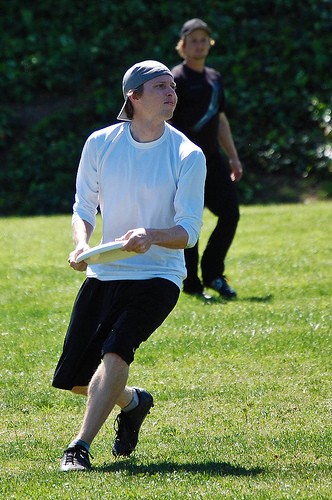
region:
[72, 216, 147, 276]
White frisbee in hands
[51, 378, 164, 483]
Man is wearing cleats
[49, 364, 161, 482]
Man's cleats are black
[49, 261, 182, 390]
Man's black athletic shorts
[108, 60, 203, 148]
Man has hat on backwards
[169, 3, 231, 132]
Man in back is standing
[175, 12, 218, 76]
Man in back is wearing hat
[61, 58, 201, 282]
Man is about to throw frisbee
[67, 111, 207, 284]
White long sleeved shirt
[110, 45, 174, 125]
Grey baseball cap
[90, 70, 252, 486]
BOY PLAYING FRISBEE ON FIELD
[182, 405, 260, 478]
SHORT GRASS ON FIELD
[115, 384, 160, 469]
BLACK CLEAT ON BOY'S FOOT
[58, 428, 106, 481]
BLACK CLEAT ON BOY'S FOOT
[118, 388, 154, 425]
GRAY SOCK ON BOY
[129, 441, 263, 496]
SHADOW OF BOY ON FIELD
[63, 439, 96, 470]
BLACK LACES ON CLEAT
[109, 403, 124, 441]
BLACK LACES ON CLEAT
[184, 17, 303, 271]
MAN IN BLACK ON FIELD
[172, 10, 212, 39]
BLACK CAP ON MAN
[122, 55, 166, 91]
Man wearing hat on head.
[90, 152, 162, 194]
Man wearing white shirt.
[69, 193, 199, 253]
Man wearing long sleeve shirt.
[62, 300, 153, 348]
Man wearing black shorts.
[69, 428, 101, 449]
Man wearing short socks.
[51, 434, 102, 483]
Man wearing black shoes.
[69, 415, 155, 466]
Man standing in grass.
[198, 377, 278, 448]
Grass on ground is green.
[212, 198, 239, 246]
Man wearing black pants.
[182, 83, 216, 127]
Man wearing black shirt.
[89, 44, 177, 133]
a man wearing his hat backwards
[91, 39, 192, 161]
a backwards gray hat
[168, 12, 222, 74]
a man wearing a hat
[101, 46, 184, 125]
a man wearing a gray hat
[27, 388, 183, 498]
black athletic cleats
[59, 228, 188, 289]
a white frisbee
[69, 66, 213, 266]
a man holding a white frisbee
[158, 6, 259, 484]
a man standing on the grass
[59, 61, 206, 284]
a man wearing a white long sleeve shirt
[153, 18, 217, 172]
a man wearing a tshirt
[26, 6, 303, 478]
two men standing on the grass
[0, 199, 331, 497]
green grass on the ground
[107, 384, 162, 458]
heel lifted off the ground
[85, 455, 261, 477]
shadow from the man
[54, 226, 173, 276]
hands on the frisbee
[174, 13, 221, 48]
black hat on the head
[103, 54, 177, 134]
hat that is on backwards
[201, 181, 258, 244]
knee is bent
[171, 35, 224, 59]
hair sticking out from under the hat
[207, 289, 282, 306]
shadow on the grass